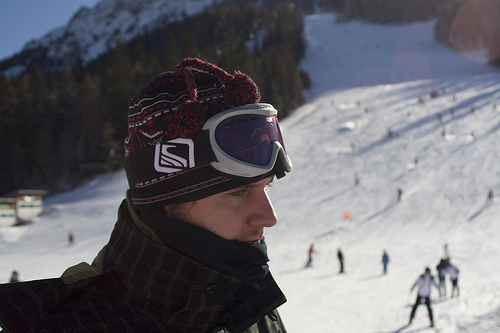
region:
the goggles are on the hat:
[192, 111, 267, 166]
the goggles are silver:
[220, 159, 253, 176]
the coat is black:
[188, 234, 219, 253]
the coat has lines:
[138, 262, 161, 292]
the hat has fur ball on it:
[170, 97, 207, 136]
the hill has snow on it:
[316, 139, 336, 161]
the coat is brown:
[83, 304, 105, 324]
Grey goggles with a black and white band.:
[126, 102, 292, 188]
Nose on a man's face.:
[248, 182, 277, 230]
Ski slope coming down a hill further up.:
[306, 12, 473, 96]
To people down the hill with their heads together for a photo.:
[435, 253, 460, 296]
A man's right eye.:
[227, 189, 244, 197]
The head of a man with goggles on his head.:
[132, 64, 278, 250]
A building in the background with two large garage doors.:
[1, 184, 51, 226]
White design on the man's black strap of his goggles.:
[153, 136, 196, 174]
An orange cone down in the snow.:
[341, 210, 351, 220]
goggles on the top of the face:
[126, 103, 301, 195]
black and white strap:
[120, 123, 216, 182]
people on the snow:
[2, 78, 497, 330]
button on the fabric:
[199, 278, 224, 297]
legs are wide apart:
[401, 295, 442, 321]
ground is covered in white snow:
[3, 76, 499, 328]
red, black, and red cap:
[112, 50, 293, 206]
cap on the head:
[116, 59, 293, 204]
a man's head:
[91, 50, 313, 293]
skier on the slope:
[378, 248, 396, 275]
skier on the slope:
[331, 245, 358, 280]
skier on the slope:
[305, 238, 319, 274]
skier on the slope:
[386, 181, 422, 208]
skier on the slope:
[348, 170, 368, 192]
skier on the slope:
[448, 256, 467, 304]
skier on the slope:
[403, 259, 443, 325]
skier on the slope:
[62, 228, 82, 250]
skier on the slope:
[5, 263, 23, 280]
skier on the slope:
[342, 167, 364, 194]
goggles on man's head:
[126, 96, 293, 202]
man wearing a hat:
[107, 54, 300, 207]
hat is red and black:
[119, 68, 294, 207]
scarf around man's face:
[141, 209, 276, 289]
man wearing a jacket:
[1, 207, 290, 329]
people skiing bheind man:
[0, 74, 497, 326]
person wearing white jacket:
[408, 274, 436, 296]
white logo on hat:
[144, 134, 198, 179]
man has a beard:
[162, 210, 192, 227]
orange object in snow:
[331, 203, 358, 233]